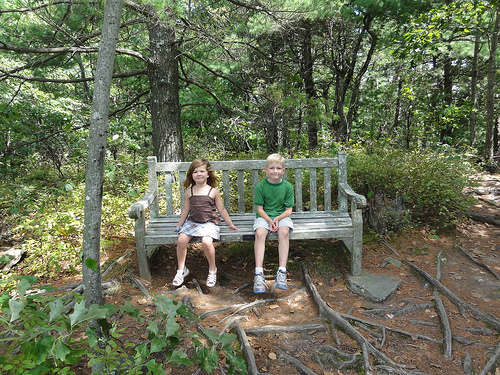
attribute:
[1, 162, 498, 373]
roots — gray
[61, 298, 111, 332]
leaf — broad, green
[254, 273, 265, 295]
shoe — blue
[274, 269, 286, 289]
shoe — blue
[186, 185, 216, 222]
top — tank top, brown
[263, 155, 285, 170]
hair — blonde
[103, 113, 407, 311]
bench — wooden, gray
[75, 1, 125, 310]
trunk — tall, thin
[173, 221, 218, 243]
skirt — short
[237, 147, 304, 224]
t-shirt — green